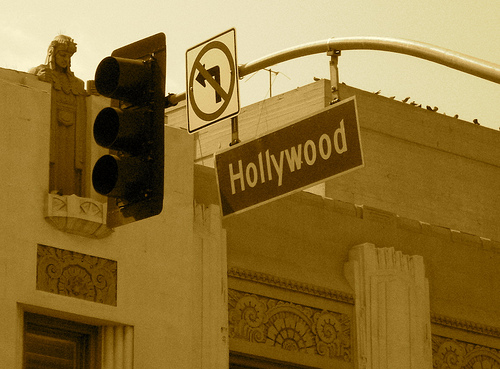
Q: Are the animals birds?
A: Yes, all the animals are birds.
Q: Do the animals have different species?
A: No, all the animals are birds.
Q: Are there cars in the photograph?
A: No, there are no cars.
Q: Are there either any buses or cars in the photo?
A: No, there are no cars or buses.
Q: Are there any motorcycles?
A: No, there are no motorcycles.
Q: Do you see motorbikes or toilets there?
A: No, there are no motorbikes or toilets.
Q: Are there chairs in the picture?
A: No, there are no chairs.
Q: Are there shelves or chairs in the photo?
A: No, there are no chairs or shelves.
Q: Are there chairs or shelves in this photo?
A: No, there are no chairs or shelves.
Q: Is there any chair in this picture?
A: No, there are no chairs.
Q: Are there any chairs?
A: No, there are no chairs.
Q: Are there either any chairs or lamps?
A: No, there are no chairs or lamps.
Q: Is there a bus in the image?
A: No, there are no buses.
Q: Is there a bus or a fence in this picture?
A: No, there are no buses or fences.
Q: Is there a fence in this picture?
A: No, there are no fences.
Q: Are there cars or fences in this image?
A: No, there are no fences or cars.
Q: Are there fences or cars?
A: No, there are no fences or cars.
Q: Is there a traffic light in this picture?
A: Yes, there is a traffic light.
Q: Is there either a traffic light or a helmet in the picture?
A: Yes, there is a traffic light.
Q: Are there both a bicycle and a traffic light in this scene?
A: No, there is a traffic light but no bicycles.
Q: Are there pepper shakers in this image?
A: No, there are no pepper shakers.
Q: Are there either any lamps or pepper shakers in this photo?
A: No, there are no pepper shakers or lamps.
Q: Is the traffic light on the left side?
A: Yes, the traffic light is on the left of the image.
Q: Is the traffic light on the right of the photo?
A: No, the traffic light is on the left of the image.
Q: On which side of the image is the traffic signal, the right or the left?
A: The traffic signal is on the left of the image.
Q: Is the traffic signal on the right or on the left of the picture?
A: The traffic signal is on the left of the image.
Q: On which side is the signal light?
A: The signal light is on the left of the image.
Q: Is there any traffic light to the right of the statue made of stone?
A: Yes, there is a traffic light to the right of the statue.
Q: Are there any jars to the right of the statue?
A: No, there is a traffic light to the right of the statue.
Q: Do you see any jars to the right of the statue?
A: No, there is a traffic light to the right of the statue.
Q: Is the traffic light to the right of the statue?
A: Yes, the traffic light is to the right of the statue.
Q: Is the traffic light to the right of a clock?
A: No, the traffic light is to the right of the statue.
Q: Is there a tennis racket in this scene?
A: No, there are no rackets.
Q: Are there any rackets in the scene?
A: No, there are no rackets.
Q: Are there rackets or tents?
A: No, there are no rackets or tents.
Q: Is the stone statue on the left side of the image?
A: Yes, the statue is on the left of the image.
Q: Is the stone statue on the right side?
A: No, the statue is on the left of the image.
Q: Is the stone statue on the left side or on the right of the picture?
A: The statue is on the left of the image.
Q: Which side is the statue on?
A: The statue is on the left of the image.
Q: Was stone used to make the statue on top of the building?
A: Yes, the statue is made of stone.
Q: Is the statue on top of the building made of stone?
A: Yes, the statue is made of stone.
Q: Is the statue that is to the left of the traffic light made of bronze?
A: No, the statue is made of stone.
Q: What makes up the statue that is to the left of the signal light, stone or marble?
A: The statue is made of stone.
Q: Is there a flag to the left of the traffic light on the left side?
A: No, there is a statue to the left of the traffic signal.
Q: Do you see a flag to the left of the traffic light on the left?
A: No, there is a statue to the left of the traffic signal.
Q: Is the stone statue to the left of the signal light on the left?
A: Yes, the statue is to the left of the traffic signal.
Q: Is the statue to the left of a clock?
A: No, the statue is to the left of the traffic signal.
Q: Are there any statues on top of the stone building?
A: Yes, there is a statue on top of the building.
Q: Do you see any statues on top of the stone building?
A: Yes, there is a statue on top of the building.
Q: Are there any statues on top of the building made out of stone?
A: Yes, there is a statue on top of the building.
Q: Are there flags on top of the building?
A: No, there is a statue on top of the building.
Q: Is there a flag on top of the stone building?
A: No, there is a statue on top of the building.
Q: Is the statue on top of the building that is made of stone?
A: Yes, the statue is on top of the building.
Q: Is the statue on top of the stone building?
A: Yes, the statue is on top of the building.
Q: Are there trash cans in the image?
A: No, there are no trash cans.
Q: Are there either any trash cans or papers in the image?
A: No, there are no trash cans or papers.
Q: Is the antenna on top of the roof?
A: Yes, the antenna is on top of the roof.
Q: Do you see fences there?
A: No, there are no fences.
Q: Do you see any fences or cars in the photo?
A: No, there are no fences or cars.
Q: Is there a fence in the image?
A: No, there are no fences.